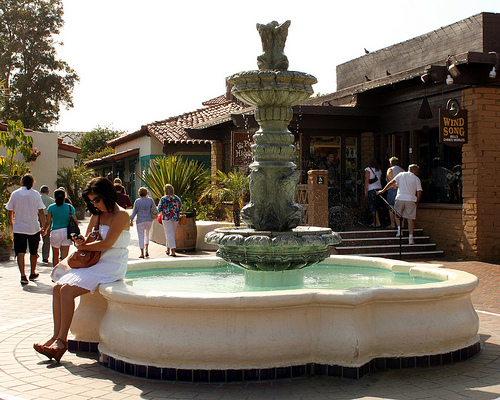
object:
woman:
[33, 177, 131, 363]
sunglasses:
[90, 195, 101, 204]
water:
[127, 265, 445, 294]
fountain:
[68, 20, 484, 379]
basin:
[68, 256, 481, 382]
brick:
[66, 336, 481, 381]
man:
[5, 173, 47, 284]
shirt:
[4, 186, 48, 234]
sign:
[439, 98, 469, 146]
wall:
[479, 91, 499, 250]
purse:
[68, 231, 104, 268]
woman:
[42, 189, 81, 267]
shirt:
[47, 202, 76, 231]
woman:
[157, 183, 183, 257]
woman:
[129, 186, 158, 258]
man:
[376, 163, 423, 245]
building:
[0, 11, 500, 259]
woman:
[364, 157, 384, 228]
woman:
[385, 156, 406, 229]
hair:
[82, 176, 117, 215]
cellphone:
[70, 233, 85, 242]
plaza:
[0, 208, 497, 398]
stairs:
[335, 229, 445, 259]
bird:
[364, 75, 370, 80]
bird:
[364, 48, 369, 54]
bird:
[386, 70, 391, 75]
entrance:
[306, 132, 362, 208]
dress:
[50, 224, 131, 294]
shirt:
[393, 171, 423, 201]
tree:
[0, 1, 79, 132]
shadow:
[38, 333, 499, 400]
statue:
[253, 20, 292, 70]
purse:
[67, 204, 80, 240]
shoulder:
[69, 204, 76, 214]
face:
[88, 193, 107, 212]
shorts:
[50, 228, 73, 248]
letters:
[443, 117, 465, 137]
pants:
[162, 220, 179, 249]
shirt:
[157, 195, 182, 221]